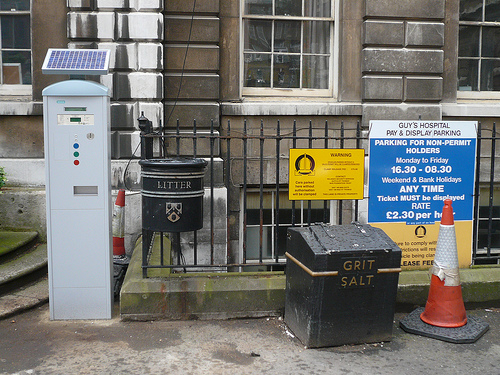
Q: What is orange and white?
A: Traffic pile on.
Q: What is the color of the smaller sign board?
A: Yellow.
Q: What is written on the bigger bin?
A: Grit Salt.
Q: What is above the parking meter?
A: Solar panel.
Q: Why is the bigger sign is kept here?
A: To show parking charges.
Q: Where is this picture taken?
A: On street.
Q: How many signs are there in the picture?
A: Two.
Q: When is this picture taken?
A: Daytime.